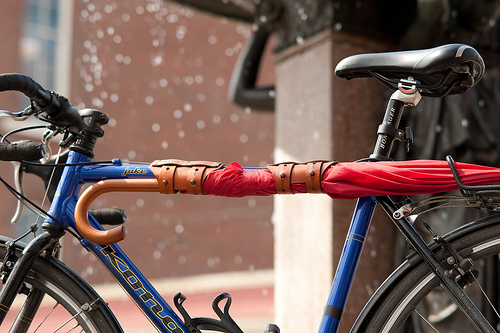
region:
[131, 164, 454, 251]
red umbrella on bike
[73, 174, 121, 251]
brown handle on umbrella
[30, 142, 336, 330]
blue frame on bike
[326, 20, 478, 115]
black seat on bike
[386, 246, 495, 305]
black wheel on bike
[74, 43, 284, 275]
red wall behind bike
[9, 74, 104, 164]
black handlebars on bike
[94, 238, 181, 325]
black name on bike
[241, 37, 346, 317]
grey corner of wall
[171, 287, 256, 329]
black water bottle holder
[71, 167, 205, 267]
the handle is orange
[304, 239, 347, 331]
the bike is blue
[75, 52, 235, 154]
rain is falling down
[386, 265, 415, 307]
the tire is black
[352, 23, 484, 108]
the seat is black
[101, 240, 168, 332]
the lettering is black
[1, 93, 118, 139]
the handles are black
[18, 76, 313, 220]
the bike has an umbrella attached to it.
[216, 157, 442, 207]
the umbrella is red.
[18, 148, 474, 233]
the umbrella is attached to the bicycle.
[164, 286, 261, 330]
cupholder on the bike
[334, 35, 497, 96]
seat on the bicycle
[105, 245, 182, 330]
brand name of bike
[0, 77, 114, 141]
handle bars on the bike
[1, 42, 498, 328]
blue bike sitting outside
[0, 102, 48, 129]
left brake on handlebar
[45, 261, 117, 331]
front black tire on bike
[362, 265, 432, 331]
rear black tire on bike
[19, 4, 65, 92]
window on a building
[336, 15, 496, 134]
the seat on a bike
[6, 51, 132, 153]
the handlebars on a bike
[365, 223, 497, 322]
the back tire on a bike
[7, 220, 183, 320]
the front on a bike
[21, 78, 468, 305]
a umbrella on a bike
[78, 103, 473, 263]
a red umbrella on a bike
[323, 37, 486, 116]
a black seat on a bike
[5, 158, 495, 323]
the wheels on a bike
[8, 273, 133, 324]
spokes on a wheel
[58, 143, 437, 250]
a umbrella strapped on a bike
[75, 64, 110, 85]
Small specks on the wall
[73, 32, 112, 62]
Small specks on the wall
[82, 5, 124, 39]
Small specks on the wall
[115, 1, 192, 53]
Small specks on the wall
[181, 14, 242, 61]
Small specks on the wall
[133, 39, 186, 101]
Small specks on the wall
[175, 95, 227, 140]
Small specks on the wall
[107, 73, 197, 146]
Small specks on the wall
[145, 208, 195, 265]
Small specks on the wall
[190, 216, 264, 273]
Small specks on the wall